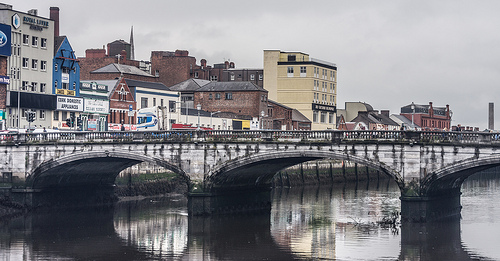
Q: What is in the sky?
A: Clouds.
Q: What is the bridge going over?
A: Water.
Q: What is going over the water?
A: Bridge.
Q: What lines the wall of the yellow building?
A: Windows.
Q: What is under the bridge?
A: Water.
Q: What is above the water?
A: Bridge.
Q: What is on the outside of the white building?
A: Business sign.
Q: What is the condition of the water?
A: Calm.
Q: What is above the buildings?
A: Sky.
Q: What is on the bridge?
A: Vehilce.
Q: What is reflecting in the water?
A: Buildings.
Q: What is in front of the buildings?
A: River.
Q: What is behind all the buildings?
A: Clouds.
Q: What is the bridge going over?
A: Water.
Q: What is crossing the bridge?
A: Cars.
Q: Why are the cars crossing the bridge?
A: To get to the other side.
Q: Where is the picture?
A: In a city.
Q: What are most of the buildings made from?
A: Brick.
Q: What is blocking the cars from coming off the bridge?
A: Railin.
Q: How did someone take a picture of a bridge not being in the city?
A: From a boat.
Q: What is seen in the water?
A: Reflection.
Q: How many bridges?
A: One.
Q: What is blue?
A: Building.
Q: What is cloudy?
A: Sky.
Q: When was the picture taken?
A: Daytime.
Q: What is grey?
A: Bridge.